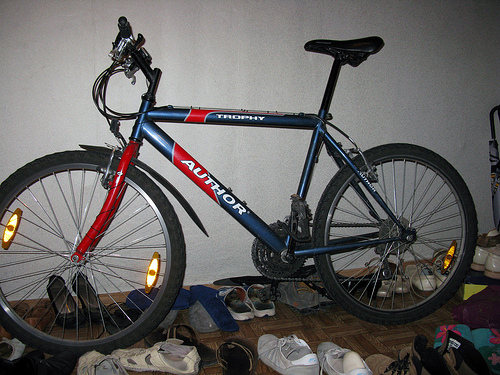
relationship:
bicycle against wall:
[1, 16, 480, 355] [0, 1, 499, 299]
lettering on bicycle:
[179, 157, 246, 218] [1, 16, 480, 355]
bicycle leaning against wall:
[1, 16, 480, 355] [0, 1, 499, 299]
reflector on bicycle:
[143, 249, 161, 293] [1, 16, 480, 355]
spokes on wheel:
[53, 169, 99, 244] [1, 149, 187, 354]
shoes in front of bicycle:
[1, 326, 499, 373] [1, 16, 480, 355]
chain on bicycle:
[251, 216, 392, 285] [1, 16, 480, 355]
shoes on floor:
[1, 326, 499, 373] [0, 246, 499, 373]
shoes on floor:
[76, 337, 199, 374] [0, 246, 499, 373]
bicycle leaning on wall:
[1, 16, 480, 355] [0, 1, 499, 299]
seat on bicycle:
[305, 34, 386, 69] [1, 16, 480, 355]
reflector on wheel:
[143, 249, 161, 293] [1, 149, 187, 354]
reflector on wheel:
[2, 207, 25, 252] [1, 149, 187, 354]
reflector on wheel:
[441, 237, 458, 273] [312, 142, 480, 324]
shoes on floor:
[256, 327, 371, 374] [0, 246, 499, 373]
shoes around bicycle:
[1, 326, 499, 373] [1, 16, 480, 355]